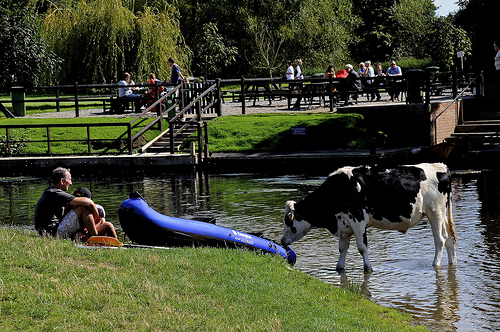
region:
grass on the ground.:
[212, 265, 249, 293]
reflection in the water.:
[428, 290, 454, 306]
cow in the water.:
[330, 156, 440, 248]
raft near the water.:
[133, 198, 222, 237]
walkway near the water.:
[230, 149, 292, 163]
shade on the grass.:
[324, 120, 341, 147]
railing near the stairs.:
[186, 91, 207, 138]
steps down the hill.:
[160, 135, 170, 149]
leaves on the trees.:
[20, 40, 47, 58]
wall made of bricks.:
[436, 109, 453, 134]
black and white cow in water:
[275, 159, 458, 282]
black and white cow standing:
[272, 146, 463, 284]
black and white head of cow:
[275, 196, 305, 242]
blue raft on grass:
[125, 199, 297, 257]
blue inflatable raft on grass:
[115, 200, 301, 265]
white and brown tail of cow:
[448, 174, 463, 245]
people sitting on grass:
[35, 157, 114, 246]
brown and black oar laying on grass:
[86, 235, 163, 252]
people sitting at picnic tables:
[270, 49, 408, 100]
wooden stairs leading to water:
[127, 93, 212, 150]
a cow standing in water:
[263, 159, 467, 292]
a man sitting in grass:
[33, 165, 96, 239]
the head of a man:
[51, 165, 72, 192]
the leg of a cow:
[425, 209, 447, 271]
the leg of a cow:
[442, 212, 466, 267]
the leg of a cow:
[336, 230, 350, 267]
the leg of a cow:
[354, 226, 380, 275]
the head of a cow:
[271, 193, 311, 248]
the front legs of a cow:
[329, 225, 379, 272]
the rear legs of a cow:
[427, 206, 462, 270]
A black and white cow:
[275, 158, 468, 279]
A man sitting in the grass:
[33, 164, 118, 248]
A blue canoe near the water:
[116, 190, 298, 279]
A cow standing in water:
[280, 158, 465, 278]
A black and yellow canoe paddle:
[84, 233, 191, 257]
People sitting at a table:
[281, 58, 413, 103]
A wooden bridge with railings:
[130, 78, 222, 168]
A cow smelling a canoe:
[116, 156, 463, 286]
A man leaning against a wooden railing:
[161, 55, 197, 120]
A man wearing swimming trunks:
[29, 163, 121, 258]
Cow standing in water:
[276, 157, 461, 277]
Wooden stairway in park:
[125, 113, 212, 152]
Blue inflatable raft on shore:
[115, 188, 294, 264]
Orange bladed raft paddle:
[77, 233, 172, 255]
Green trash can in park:
[10, 83, 26, 113]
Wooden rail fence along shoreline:
[2, 120, 141, 157]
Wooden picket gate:
[179, 76, 223, 116]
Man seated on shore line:
[32, 165, 113, 245]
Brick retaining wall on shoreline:
[333, 104, 463, 144]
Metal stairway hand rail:
[425, 77, 473, 147]